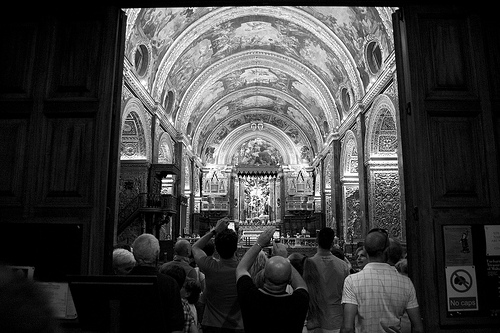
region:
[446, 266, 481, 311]
a sign on the wall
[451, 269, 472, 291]
a hat with a line through it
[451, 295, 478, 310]
a sign reading no caps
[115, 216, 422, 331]
a group of people admiring the ceiling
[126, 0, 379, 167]
a beautiful arched ceiling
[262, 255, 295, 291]
the back of a bald man's head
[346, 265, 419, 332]
a white checkered shirt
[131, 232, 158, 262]
a head of gray hair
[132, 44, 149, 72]
a hole on the ceiling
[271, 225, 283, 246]
a cellphone held up to take a picture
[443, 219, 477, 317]
sign on a doorway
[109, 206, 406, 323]
crowd taking pictures in church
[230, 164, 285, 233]
back of a church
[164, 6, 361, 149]
ceiling of a church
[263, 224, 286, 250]
phone taking a picture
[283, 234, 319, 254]
pews in a church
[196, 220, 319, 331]
two men with camera phones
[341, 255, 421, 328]
short sleeve shirt on a man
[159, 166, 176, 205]
light on a wall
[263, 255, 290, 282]
bald head of man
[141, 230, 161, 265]
white hair on head of man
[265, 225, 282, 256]
hands holding cell phone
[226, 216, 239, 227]
hands holding cell phone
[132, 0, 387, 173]
mural on the ceiling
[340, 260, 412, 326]
white checkered shirt on man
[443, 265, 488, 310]
white sign on the wall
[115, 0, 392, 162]
large arched building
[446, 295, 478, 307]
white writing on sign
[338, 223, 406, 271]
glasses on a person's head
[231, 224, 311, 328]
a person taking a picture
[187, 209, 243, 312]
a person holding a phone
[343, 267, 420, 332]
shirt with a checkered pattern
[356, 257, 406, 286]
collar on a golf shirt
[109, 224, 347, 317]
people facing the other way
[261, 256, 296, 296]
man with a bold head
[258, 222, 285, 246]
smart phone in a man's hands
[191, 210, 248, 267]
the back of a person's head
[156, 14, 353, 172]
artwork on a curved ceiling